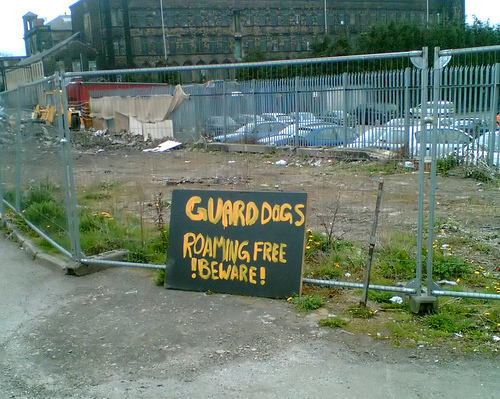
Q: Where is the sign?
A: Front of fence.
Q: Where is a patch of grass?
A: Behind the sign.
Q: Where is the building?
A: Background.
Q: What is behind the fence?
A: Parking lot.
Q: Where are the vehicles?
A: Parking lot.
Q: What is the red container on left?
A: Dumpster.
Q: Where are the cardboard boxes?
A: Next to dumpster.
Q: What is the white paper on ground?
A: Trash.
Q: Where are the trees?
A: Right of building.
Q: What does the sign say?
A: Guard dogs roaming free ! beware .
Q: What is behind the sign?
A: Fence.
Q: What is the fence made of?
A: Metal.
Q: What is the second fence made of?
A: Metal.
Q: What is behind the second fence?
A: Cars.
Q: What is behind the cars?
A: Trees.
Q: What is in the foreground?
A: Gravel.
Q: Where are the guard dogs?
A: Roaming free.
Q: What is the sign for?
A: Warning.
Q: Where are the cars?
A: Behind fence.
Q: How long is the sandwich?
A: No sandwich.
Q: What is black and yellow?
A: Sign.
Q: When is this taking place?
A: Daytime.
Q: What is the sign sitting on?
A: Cement ground.